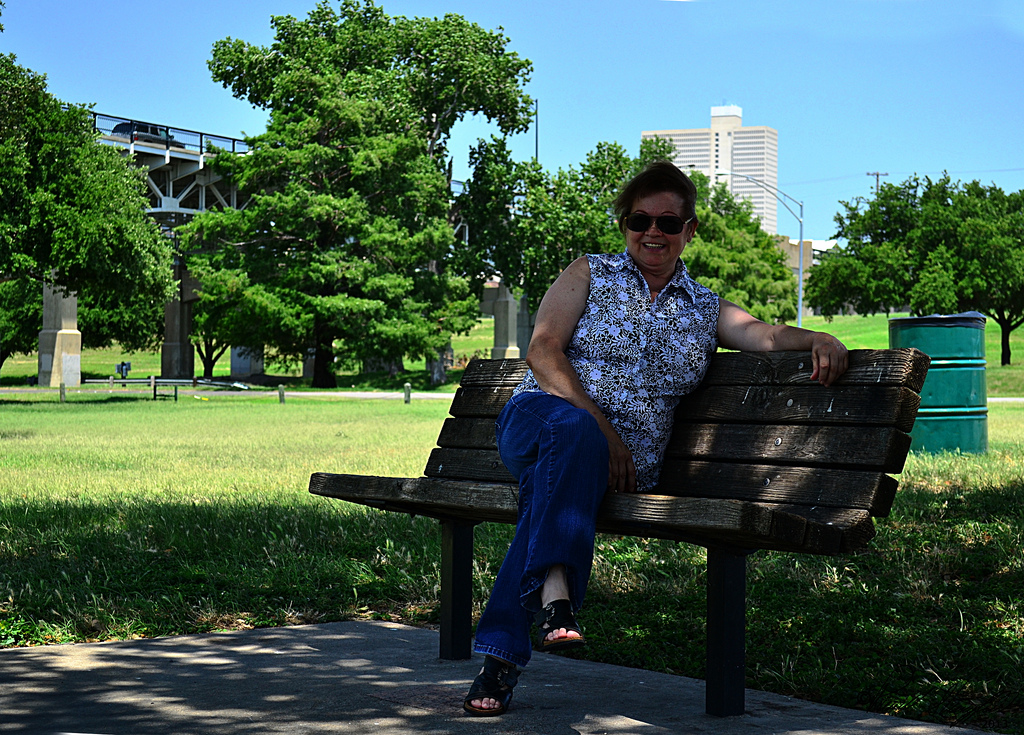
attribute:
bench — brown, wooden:
[342, 340, 909, 645]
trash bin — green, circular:
[894, 307, 1008, 448]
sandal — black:
[517, 586, 597, 643]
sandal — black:
[445, 640, 518, 714]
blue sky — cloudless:
[544, 17, 1019, 125]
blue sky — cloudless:
[496, 1, 1016, 142]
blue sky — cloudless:
[544, 14, 1012, 174]